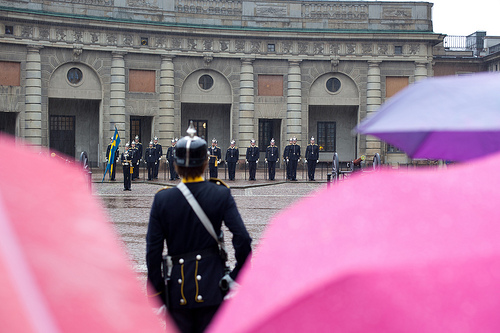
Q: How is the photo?
A: Clear.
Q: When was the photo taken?
A: Daytime.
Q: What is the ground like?
A: Wet.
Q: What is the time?
A: Morning.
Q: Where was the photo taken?
A: In a city square.